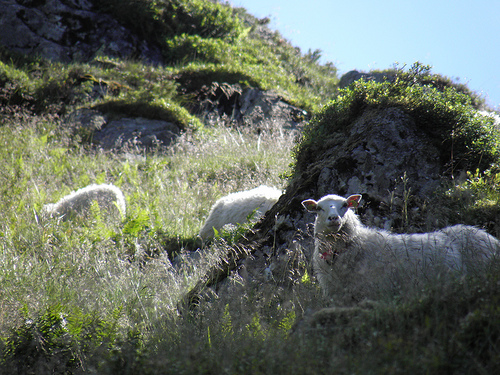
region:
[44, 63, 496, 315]
There are lamb in the photo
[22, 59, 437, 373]
There is grass in the photo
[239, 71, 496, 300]
There are rocks covered grass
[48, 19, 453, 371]
The photo was taken on a sunny day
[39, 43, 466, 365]
The lamb are on a hill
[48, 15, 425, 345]
The lamb are on a hillside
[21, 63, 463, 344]
There are three lamb in the photo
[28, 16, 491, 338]
The photo was taken in the daytime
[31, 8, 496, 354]
The photo was not taken at night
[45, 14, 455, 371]
It is raining in the photo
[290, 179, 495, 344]
Sheep lying in the meadow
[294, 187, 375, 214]
Pointy ears of sheep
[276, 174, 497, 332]
Sheep is white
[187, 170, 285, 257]
Sheep in the field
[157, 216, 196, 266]
Shadow of sheep cast on the grass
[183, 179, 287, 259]
Sheep eating grass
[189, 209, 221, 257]
Neck of sheep is down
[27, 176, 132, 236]
Sheep is in the middle of grass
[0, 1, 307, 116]
Mountain is cover with grass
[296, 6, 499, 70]
Ski is blue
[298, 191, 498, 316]
sheep on lower right side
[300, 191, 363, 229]
head of sheep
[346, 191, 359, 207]
left ear of the sheep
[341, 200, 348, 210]
left eye of the sheep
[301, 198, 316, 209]
right ear of the sheep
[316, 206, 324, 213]
right eye of the sheep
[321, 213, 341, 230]
nose and mouth of the sheep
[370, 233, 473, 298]
body of the sheep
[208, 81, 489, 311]
rock formation behind the sheep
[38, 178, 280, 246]
two sheep eating in the background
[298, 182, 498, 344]
Large white mountain sheep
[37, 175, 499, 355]
Three mountain sheep grazing in the mountains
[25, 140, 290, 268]
Two sheep grazing on the grass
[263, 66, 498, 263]
Large boulder with foliage growing on it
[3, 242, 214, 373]
Bushes of greenery growing on the mountain side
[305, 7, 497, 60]
Clear blue sky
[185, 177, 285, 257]
Sheep with it's head buried behind the tall grass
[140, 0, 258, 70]
Large bush growing on a boulder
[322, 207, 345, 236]
Mouth and nose of the mountain sheep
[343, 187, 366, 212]
Sheep's ear with a tag in it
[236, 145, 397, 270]
sheep looks toward camera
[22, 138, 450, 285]
three sheep but only two grazing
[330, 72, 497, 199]
Rocky soil beneath grass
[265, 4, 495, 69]
clear blue sky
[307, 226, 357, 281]
Something red shows on sheep's throat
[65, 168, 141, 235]
a sheep's rump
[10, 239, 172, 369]
Very long grass and brush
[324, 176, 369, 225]
An identification tag on sheep's ear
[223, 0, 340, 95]
the ridge of the hill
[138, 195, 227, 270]
A grazing sheep's shadow